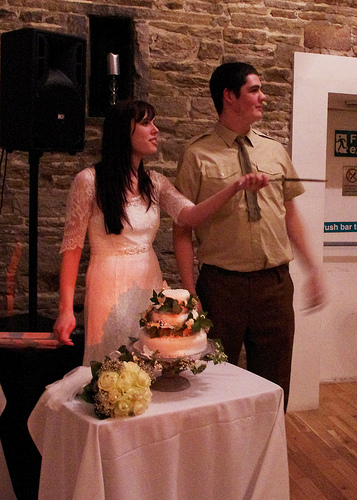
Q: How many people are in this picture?
A: Two.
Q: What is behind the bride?
A: A speaker.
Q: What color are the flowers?
A: Yellow.